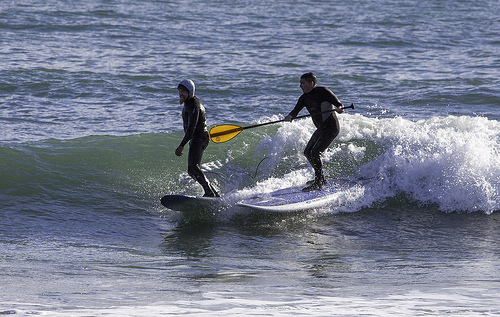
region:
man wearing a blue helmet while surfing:
[162, 76, 225, 206]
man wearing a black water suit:
[270, 64, 356, 191]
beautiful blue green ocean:
[1, 0, 498, 314]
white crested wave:
[239, 101, 499, 229]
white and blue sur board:
[239, 165, 391, 230]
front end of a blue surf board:
[156, 173, 244, 225]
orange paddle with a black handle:
[205, 99, 359, 152]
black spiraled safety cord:
[195, 150, 277, 188]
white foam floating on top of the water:
[0, 283, 499, 311]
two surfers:
[162, 62, 372, 222]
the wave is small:
[56, 82, 454, 273]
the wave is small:
[70, 87, 256, 240]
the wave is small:
[77, 60, 179, 205]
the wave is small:
[93, 107, 213, 275]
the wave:
[330, 58, 430, 231]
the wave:
[295, 110, 406, 232]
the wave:
[334, 129, 388, 304]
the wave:
[342, 163, 417, 304]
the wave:
[342, 212, 384, 304]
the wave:
[321, 102, 445, 298]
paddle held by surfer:
[201, 96, 242, 146]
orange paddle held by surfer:
[210, 123, 245, 151]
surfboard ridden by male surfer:
[249, 172, 306, 225]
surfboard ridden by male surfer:
[167, 189, 224, 216]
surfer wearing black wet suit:
[289, 89, 341, 176]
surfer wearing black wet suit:
[177, 103, 208, 179]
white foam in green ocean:
[401, 113, 473, 213]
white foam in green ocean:
[346, 113, 388, 193]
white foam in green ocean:
[26, 263, 296, 314]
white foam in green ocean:
[264, 276, 451, 314]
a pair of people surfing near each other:
[63, 49, 428, 248]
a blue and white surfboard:
[237, 149, 385, 225]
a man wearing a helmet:
[166, 62, 225, 212]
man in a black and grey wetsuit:
[271, 60, 360, 195]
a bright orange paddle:
[202, 114, 255, 146]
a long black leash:
[192, 149, 276, 184]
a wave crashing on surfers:
[128, 104, 488, 222]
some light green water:
[3, 87, 160, 252]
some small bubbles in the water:
[220, 283, 425, 315]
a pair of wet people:
[126, 59, 403, 232]